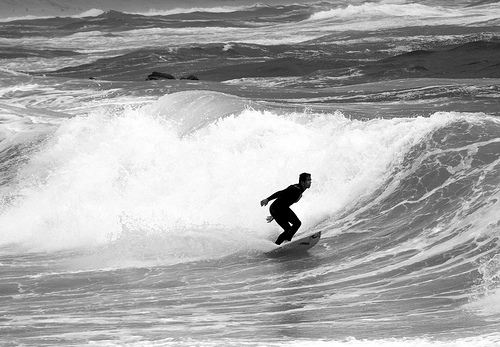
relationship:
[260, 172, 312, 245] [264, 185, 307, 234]
guy wears swim suit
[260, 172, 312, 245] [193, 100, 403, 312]
guy in ocean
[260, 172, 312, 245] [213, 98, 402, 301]
guy in ocean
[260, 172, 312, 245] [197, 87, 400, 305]
guy in ocean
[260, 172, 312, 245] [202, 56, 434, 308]
guy in ocean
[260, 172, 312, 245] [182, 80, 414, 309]
guy in ocean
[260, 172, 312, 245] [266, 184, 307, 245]
guy wears swim suit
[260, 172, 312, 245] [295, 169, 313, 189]
guy has hair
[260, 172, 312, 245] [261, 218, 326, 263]
guy on surfboard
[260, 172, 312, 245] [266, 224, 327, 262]
guy on surfboard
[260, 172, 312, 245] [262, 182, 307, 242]
guy wears wet suit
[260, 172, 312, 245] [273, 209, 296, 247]
guy has leg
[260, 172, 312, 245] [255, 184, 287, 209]
guy has arm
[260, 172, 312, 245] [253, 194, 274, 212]
guy has hand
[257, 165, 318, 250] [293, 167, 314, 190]
guy has hair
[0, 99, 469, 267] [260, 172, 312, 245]
spray behind guy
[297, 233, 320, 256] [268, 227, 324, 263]
design on surfboard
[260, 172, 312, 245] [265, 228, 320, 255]
guy on a surfboard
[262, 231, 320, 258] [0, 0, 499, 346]
surfboard in ocean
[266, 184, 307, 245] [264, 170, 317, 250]
swim suit on a surfer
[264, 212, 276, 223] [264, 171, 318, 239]
left hand of a surfer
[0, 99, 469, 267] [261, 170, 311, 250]
spray behind man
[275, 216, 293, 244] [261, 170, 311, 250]
leg of man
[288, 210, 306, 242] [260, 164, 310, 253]
left leg of man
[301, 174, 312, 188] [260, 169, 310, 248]
head of surfer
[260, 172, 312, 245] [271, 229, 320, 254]
guy on a surfboard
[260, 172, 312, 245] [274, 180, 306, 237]
guy wearing a wetsuit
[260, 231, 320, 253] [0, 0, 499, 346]
surfboard in ocean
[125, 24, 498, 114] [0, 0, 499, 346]
ripples in ocean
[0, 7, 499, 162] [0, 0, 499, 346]
ripples in ocean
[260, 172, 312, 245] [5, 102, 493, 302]
guy on wave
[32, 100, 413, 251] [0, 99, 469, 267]
spray on spray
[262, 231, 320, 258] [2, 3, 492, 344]
surfboard in ocean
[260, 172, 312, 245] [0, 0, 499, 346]
guy in ocean